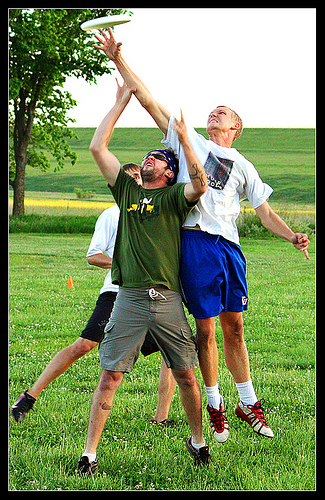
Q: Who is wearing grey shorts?
A: The man in the green t-shirt.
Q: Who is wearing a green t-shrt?
A: The man in grey shorts.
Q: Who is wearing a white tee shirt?
A: The man on the right.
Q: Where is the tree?
A: On the left.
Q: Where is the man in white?
A: Behind the other men.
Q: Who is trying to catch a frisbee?
A: The men.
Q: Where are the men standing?
A: In a field of green grass and small flowers.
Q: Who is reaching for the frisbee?
A: The man in the green shirt.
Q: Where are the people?
A: In grass.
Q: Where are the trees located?
A: In grass.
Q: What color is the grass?
A: Green.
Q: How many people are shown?
A: Three.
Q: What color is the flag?
A: Orange.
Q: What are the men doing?
A: Playing frisbee.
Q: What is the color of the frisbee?
A: White.